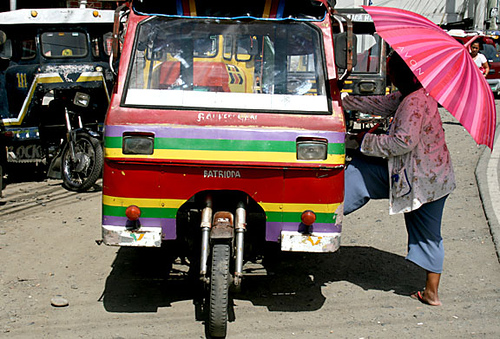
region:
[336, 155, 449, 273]
Woman is wearing pants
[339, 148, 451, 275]
Woman is wearing blue pants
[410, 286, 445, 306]
Woman is wearing shoes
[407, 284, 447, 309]
Woman is wearing sandals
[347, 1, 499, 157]
Woman is holding an umbrella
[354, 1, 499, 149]
Woman is holding a pink striped umbrella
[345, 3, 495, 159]
Woman is carrying an umbrella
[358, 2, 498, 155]
Woman is carrying a pink striped umbrella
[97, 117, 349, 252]
Stripes on front of the vehicle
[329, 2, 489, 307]
Woman is climbing into vehicle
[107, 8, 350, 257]
the vehicle is multi colored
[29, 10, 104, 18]
two lights are on top of the vehicle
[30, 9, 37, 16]
the light is yellow in color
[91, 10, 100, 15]
the light is yellow in color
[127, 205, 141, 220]
the light is red in color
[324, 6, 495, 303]
the woman is getting into the vehicle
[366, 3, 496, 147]
the umbrella is red in color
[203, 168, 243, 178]
lettering is on the vehicle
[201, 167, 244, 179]
the lettering is white in color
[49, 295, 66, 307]
a rock is on the ground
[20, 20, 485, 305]
A motor cab is picking someone up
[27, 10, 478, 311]
A motor cab is on the street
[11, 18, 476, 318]
People are out in the sunshine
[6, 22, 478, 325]
The person is going to work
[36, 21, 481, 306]
A person is going shopping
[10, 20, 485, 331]
The person has an umbrella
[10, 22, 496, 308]
An umbrella is being used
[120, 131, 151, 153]
The headlight of a motor cab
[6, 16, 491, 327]
Many motor cabs are on the street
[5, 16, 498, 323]
People are enjoying their day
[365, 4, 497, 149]
bright pink and purple stripped umbrella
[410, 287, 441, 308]
bright pink flip flop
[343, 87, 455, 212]
white sweater with flower pattern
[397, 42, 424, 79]
4 pink letters that read AVON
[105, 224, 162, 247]
white metal bumper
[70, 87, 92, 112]
single motorcycle headlight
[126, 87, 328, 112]
bright white stripe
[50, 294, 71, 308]
small round flat rock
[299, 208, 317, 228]
small round red turn signal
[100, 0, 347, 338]
red yellow green and red striped cart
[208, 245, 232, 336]
the tire is made of rubber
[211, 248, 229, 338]
the tire is black in color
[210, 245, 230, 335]
the tire is old and worn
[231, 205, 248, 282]
shock absorbers are attatched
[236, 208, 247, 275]
the shock absorbers are made of metal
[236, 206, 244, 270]
the shock absorber is grey in color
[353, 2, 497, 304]
the woman is holding an umbrella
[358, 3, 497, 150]
the umbrella is in an open position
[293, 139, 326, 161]
a headlight is in front of the vehicle